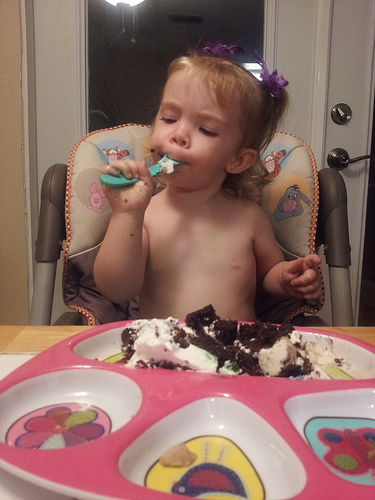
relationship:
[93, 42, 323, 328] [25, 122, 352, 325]
child sitting in high chair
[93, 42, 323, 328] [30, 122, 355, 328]
child sitting in chair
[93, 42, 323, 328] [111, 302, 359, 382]
child eating a cake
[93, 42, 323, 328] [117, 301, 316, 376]
child eating a cake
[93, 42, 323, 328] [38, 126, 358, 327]
child sitting in chair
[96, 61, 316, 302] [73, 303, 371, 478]
child eating cake